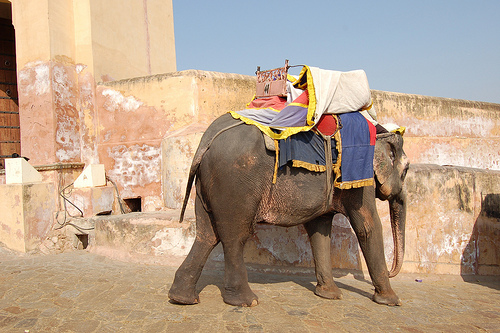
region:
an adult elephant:
[172, 109, 404, 307]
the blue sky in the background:
[207, 8, 445, 45]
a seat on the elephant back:
[253, 63, 359, 116]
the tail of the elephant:
[177, 163, 197, 225]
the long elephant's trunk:
[387, 198, 407, 277]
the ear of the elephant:
[371, 142, 398, 182]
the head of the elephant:
[376, 132, 410, 197]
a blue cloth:
[342, 131, 366, 177]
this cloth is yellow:
[304, 65, 368, 111]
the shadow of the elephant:
[190, 223, 370, 308]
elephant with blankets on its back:
[159, 58, 415, 312]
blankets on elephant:
[232, 98, 379, 190]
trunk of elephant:
[383, 180, 410, 278]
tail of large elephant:
[177, 135, 202, 222]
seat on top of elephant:
[252, 58, 317, 108]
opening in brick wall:
[119, 193, 146, 213]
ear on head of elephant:
[370, 131, 400, 191]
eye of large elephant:
[400, 158, 411, 183]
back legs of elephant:
[164, 200, 260, 310]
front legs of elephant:
[303, 199, 398, 307]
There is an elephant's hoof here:
[238, 288, 258, 325]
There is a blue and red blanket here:
[345, 130, 360, 173]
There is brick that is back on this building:
[5, 115, 15, 153]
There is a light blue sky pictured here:
[408, 33, 430, 67]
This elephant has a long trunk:
[388, 199, 432, 293]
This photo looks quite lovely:
[120, 41, 289, 217]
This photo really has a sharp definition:
[88, 50, 381, 304]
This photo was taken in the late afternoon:
[102, 53, 373, 323]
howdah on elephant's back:
[245, 60, 367, 137]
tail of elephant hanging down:
[176, 153, 199, 221]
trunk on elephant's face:
[386, 190, 406, 276]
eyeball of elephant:
[400, 162, 405, 172]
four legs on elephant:
[163, 212, 409, 308]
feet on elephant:
[165, 282, 398, 305]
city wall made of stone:
[95, 68, 495, 273]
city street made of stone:
[2, 252, 490, 329]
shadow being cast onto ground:
[460, 190, 499, 291]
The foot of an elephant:
[227, 290, 252, 302]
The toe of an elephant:
[252, 302, 257, 304]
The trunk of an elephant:
[396, 208, 401, 271]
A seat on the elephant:
[258, 76, 280, 94]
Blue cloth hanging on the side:
[345, 141, 368, 176]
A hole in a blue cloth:
[315, 159, 320, 163]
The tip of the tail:
[180, 217, 182, 220]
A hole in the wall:
[128, 201, 138, 209]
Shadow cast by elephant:
[258, 267, 305, 279]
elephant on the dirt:
[132, 79, 438, 306]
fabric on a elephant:
[329, 117, 381, 197]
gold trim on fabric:
[325, 113, 393, 202]